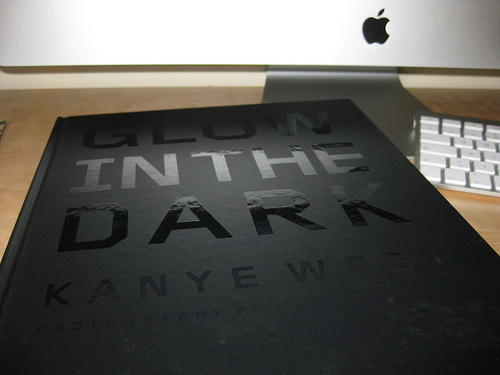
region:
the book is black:
[1, 98, 498, 373]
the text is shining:
[48, 108, 411, 252]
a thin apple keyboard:
[411, 110, 498, 198]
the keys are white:
[420, 115, 499, 190]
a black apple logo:
[362, 6, 391, 44]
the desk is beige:
[0, 88, 497, 374]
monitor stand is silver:
[260, 65, 437, 156]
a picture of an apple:
[361, 9, 391, 44]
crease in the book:
[0, 115, 65, 294]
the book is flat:
[0, 99, 499, 374]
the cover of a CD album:
[18, 64, 475, 373]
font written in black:
[59, 117, 336, 151]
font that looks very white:
[78, 145, 346, 185]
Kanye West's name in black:
[48, 250, 460, 315]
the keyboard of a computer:
[418, 100, 499, 192]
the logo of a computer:
[349, 12, 411, 52]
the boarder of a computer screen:
[57, 21, 157, 87]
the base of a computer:
[233, 77, 426, 154]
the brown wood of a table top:
[8, 89, 53, 149]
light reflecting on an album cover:
[78, 124, 232, 256]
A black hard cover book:
[1, 96, 498, 374]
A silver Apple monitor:
[0, 0, 499, 158]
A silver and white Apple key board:
[414, 108, 499, 197]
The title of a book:
[53, 103, 410, 233]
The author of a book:
[35, 240, 447, 310]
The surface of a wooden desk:
[0, 87, 499, 267]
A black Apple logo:
[361, 6, 392, 46]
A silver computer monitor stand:
[261, 66, 438, 156]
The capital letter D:
[57, 201, 132, 253]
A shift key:
[419, 151, 447, 166]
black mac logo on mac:
[348, 5, 403, 49]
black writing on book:
[24, 92, 382, 356]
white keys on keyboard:
[417, 109, 494, 183]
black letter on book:
[5, 265, 86, 329]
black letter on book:
[181, 263, 219, 307]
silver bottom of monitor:
[0, 2, 335, 77]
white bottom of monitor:
[21, 11, 362, 58]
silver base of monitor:
[260, 72, 402, 106]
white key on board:
[441, 168, 468, 188]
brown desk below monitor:
[0, 75, 62, 145]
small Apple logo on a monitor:
[363, 6, 390, 46]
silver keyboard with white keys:
[413, 109, 499, 196]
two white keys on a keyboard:
[419, 115, 440, 134]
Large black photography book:
[1, 99, 498, 374]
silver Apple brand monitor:
[3, 0, 498, 160]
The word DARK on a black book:
[55, 180, 413, 251]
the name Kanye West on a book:
[42, 243, 444, 306]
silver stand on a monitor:
[260, 65, 434, 159]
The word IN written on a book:
[67, 152, 179, 192]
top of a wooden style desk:
[1, 90, 499, 260]